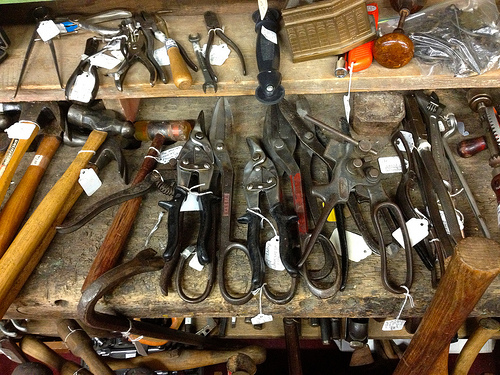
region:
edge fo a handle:
[253, 273, 277, 320]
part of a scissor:
[219, 273, 260, 340]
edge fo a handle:
[311, 275, 341, 326]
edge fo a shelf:
[288, 299, 330, 357]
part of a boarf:
[274, 300, 298, 328]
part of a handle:
[291, 263, 316, 310]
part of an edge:
[242, 269, 268, 301]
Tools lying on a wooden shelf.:
[5, 52, 490, 364]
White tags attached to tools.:
[1, 0, 496, 370]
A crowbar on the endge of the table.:
[70, 246, 341, 351]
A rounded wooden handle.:
[391, 234, 499, 372]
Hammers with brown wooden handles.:
[0, 101, 133, 316]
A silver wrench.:
[180, 25, 220, 95]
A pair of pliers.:
[190, 7, 250, 83]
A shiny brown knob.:
[371, 20, 416, 71]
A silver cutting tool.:
[175, 95, 250, 305]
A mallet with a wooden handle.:
[81, 106, 190, 298]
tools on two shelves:
[6, 16, 498, 284]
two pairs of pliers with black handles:
[162, 114, 289, 279]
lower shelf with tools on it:
[3, 108, 492, 310]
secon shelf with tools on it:
[10, 10, 488, 102]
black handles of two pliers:
[156, 184, 311, 285]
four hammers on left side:
[3, 99, 134, 306]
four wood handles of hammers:
[6, 133, 91, 305]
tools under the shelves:
[8, 320, 457, 373]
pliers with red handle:
[258, 102, 313, 257]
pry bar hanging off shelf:
[73, 260, 322, 357]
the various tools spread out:
[0, 0, 498, 374]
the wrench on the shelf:
[186, 32, 216, 93]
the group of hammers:
[3, 102, 191, 314]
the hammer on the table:
[1, 103, 133, 324]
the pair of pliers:
[162, 110, 214, 267]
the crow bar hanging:
[75, 248, 247, 352]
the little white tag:
[78, 166, 102, 196]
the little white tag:
[382, 318, 406, 330]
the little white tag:
[378, 154, 407, 176]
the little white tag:
[330, 226, 372, 261]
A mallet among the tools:
[88, 121, 188, 298]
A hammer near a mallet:
[0, 100, 136, 287]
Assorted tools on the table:
[1, 94, 483, 304]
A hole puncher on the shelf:
[110, 30, 162, 82]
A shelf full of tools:
[3, 18, 497, 82]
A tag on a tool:
[385, 292, 411, 331]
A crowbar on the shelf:
[81, 248, 320, 347]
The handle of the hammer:
[0, 130, 109, 289]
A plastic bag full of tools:
[410, 10, 495, 73]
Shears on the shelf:
[181, 99, 253, 299]